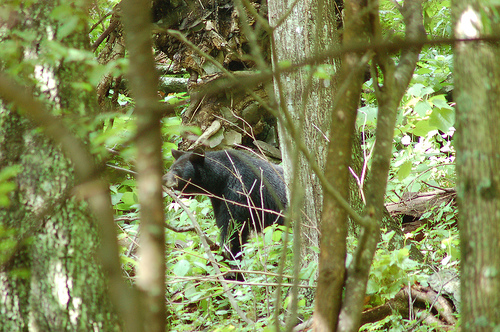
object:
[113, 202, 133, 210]
leaves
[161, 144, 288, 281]
bear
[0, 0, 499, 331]
natural habitat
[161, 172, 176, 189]
snout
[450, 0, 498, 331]
bark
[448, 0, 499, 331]
trunk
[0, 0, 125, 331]
trunk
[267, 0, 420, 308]
trunk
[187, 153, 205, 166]
ears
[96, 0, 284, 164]
hillside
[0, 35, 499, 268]
blurred twig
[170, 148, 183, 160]
ear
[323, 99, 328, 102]
lichen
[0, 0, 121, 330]
trees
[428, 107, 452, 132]
frond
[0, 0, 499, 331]
bushes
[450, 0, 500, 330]
tree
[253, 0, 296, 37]
twig